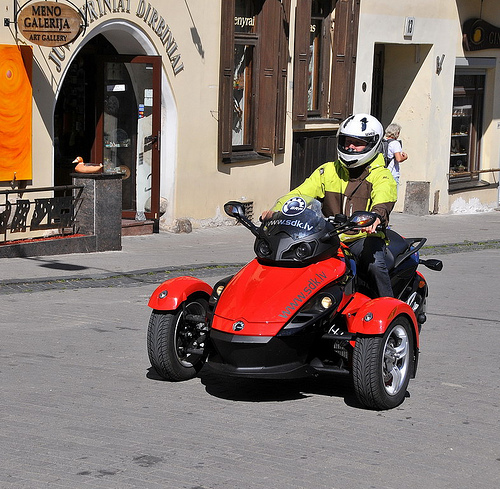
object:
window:
[231, 41, 250, 146]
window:
[305, 34, 316, 116]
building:
[0, 0, 499, 259]